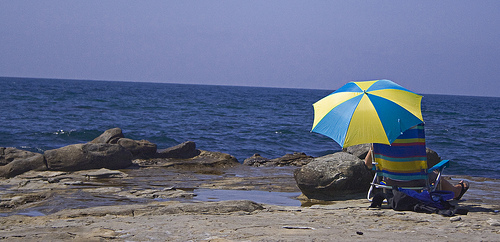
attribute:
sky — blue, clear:
[5, 1, 405, 75]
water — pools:
[0, 169, 301, 233]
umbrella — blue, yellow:
[292, 76, 433, 149]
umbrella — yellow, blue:
[298, 70, 448, 160]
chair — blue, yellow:
[361, 142, 441, 201]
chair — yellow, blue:
[363, 131, 456, 231]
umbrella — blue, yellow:
[306, 77, 431, 168]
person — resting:
[383, 134, 474, 234]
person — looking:
[380, 123, 474, 213]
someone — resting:
[347, 93, 481, 231]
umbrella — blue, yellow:
[314, 72, 419, 142]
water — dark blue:
[126, 95, 204, 134]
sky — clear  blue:
[43, 60, 409, 89]